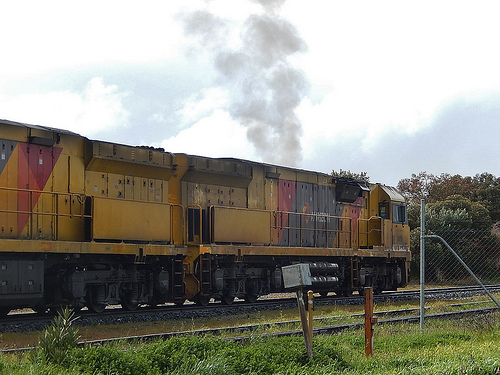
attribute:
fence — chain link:
[345, 170, 468, 331]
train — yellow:
[2, 112, 420, 322]